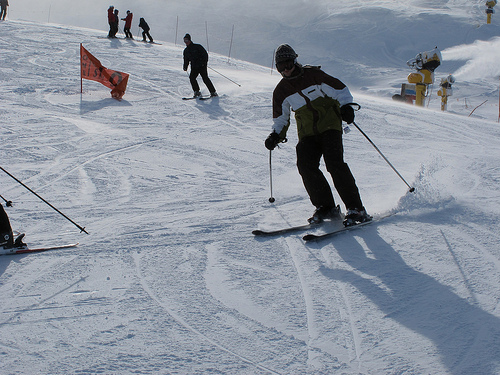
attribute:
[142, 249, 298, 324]
snow — here, packed down, white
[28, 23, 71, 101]
hill — here, beautiful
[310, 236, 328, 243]
board — here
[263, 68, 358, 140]
jacket — here, brown white, gree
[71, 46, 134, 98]
flag — here, orange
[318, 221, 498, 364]
shadow — here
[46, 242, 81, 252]
skate — here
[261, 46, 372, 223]
man — skiing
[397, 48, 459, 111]
machines — yellow, white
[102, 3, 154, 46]
four skiers — together, talking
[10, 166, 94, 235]
ski pole — black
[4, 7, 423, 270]
people — skiing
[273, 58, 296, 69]
goggles — black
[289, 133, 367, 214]
pants — black